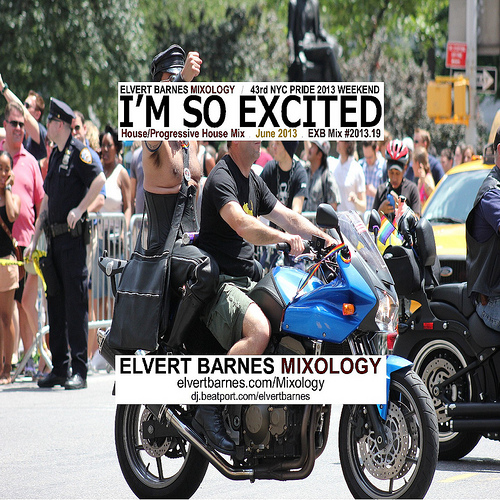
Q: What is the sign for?
A: Event.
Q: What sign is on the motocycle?
A: Elvert barns mixology.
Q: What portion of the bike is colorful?
A: Blue front.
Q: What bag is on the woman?
A: Black messenger bag.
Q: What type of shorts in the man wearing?
A: Green shorts.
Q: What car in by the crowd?
A: A yellow car.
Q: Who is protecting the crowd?
A: A police officer.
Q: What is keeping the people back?
A: A metal fence.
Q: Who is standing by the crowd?
A: A police officer.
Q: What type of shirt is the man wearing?
A: A pink polo shirt.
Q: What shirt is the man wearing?
A: A black t shirt.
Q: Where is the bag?
A: Across the body.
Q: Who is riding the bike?
A: A man with black T-shirt.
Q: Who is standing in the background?
A: A crowd.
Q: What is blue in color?
A: The bike.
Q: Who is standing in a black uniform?
A: A policemen.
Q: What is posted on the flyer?
A: Website address.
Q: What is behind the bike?
A: A car.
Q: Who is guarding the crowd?
A: The police officer.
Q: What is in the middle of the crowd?
A: A taxi cab.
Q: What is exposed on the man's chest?
A: Nipples.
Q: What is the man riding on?
A: Motorcycle.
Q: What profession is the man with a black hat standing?
A: Police officer.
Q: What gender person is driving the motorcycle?
A: Male.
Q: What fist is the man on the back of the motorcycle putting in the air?
A: Right.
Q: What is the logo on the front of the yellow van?
A: Ford.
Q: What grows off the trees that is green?
A: Leaves.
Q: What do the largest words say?
A: I'M SO EXCITED.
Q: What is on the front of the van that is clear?
A: Windshield.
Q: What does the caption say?
A: I'm so excited.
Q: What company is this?
A: Elvert Barnes Mixology.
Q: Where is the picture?
A: City street.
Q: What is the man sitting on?
A: Motorcycle.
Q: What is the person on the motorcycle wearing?
A: Shirt and shorts.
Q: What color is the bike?
A: Blue.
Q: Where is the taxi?
A: In the crowd.